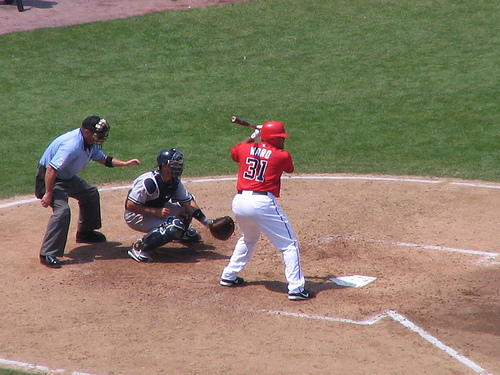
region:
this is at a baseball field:
[21, 24, 436, 361]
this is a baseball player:
[233, 115, 310, 287]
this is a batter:
[203, 109, 312, 306]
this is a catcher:
[132, 145, 224, 260]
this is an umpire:
[54, 109, 118, 280]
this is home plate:
[304, 252, 389, 321]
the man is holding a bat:
[191, 118, 312, 311]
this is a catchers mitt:
[196, 197, 241, 254]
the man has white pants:
[199, 173, 306, 307]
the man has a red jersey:
[228, 147, 302, 198]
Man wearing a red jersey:
[232, 125, 297, 187]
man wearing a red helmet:
[245, 111, 313, 163]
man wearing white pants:
[227, 185, 316, 274]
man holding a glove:
[197, 209, 242, 244]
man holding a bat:
[231, 104, 269, 150]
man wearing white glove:
[246, 125, 269, 148]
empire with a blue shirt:
[46, 126, 84, 191]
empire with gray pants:
[28, 186, 90, 236]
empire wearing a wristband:
[97, 153, 124, 177]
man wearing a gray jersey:
[124, 173, 182, 231]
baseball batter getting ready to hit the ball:
[219, 93, 335, 303]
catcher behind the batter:
[125, 128, 230, 295]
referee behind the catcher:
[37, 78, 137, 295]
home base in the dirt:
[330, 243, 372, 325]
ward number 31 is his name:
[242, 143, 272, 188]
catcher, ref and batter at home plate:
[19, 30, 449, 373]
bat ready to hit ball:
[228, 104, 260, 134]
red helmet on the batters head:
[254, 118, 293, 155]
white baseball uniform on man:
[218, 188, 308, 313]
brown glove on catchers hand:
[204, 195, 239, 251]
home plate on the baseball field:
[326, 266, 380, 299]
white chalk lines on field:
[394, 309, 497, 373]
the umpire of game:
[35, 115, 130, 270]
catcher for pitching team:
[126, 151, 237, 264]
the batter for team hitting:
[225, 115, 310, 300]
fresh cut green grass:
[408, 48, 496, 133]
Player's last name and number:
[235, 146, 276, 186]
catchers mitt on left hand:
[209, 215, 241, 242]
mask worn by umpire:
[96, 120, 112, 147]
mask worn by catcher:
[164, 148, 186, 178]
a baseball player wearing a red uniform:
[213, 94, 331, 329]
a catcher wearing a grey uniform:
[128, 150, 222, 256]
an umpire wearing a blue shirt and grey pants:
[21, 116, 118, 260]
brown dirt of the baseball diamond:
[60, 277, 170, 342]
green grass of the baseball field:
[346, 45, 432, 140]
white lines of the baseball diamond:
[356, 303, 460, 374]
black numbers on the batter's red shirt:
[235, 155, 270, 188]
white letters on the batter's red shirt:
[243, 147, 275, 158]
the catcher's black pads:
[154, 180, 174, 203]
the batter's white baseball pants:
[217, 192, 317, 295]